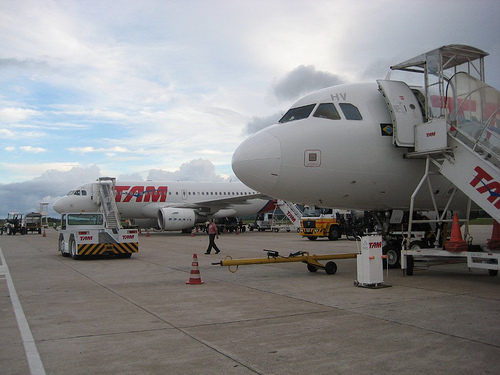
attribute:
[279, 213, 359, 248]
truck — yellow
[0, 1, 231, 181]
clouds — White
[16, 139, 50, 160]
cloud — white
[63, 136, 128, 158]
cloud — white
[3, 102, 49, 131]
cloud — white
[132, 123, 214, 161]
cloud — white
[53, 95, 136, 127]
cloud — white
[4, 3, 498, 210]
sky — blue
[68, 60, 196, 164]
clouds — white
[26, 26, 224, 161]
clouds — White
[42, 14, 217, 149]
clouds — white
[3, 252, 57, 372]
lines — White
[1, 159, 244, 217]
clouds — White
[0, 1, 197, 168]
clouds — White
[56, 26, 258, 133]
clouds — White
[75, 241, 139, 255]
stripes — yellow, black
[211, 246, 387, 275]
equipment — yellow, wheeled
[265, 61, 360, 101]
clouds — white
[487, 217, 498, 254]
cone — orange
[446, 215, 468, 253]
cone — orange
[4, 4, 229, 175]
sky — blue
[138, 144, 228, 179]
clouds — white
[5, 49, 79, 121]
clouds — white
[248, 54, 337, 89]
clouds — white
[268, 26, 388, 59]
clouds — White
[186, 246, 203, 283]
cone — white, striped, orange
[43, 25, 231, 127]
clouds — white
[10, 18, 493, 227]
clouds — White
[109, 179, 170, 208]
text — red